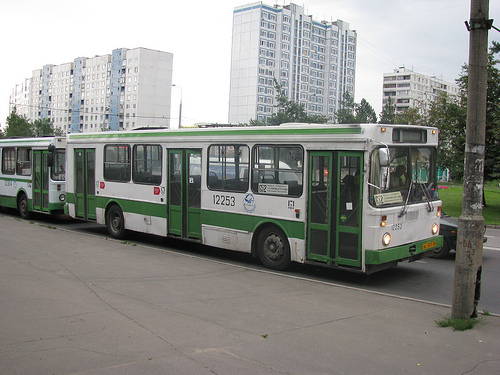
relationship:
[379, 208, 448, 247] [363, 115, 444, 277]
lights on on front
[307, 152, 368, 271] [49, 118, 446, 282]
doors on bus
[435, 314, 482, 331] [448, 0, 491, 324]
grass around pole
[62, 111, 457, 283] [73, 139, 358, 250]
bus has doors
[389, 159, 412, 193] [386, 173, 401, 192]
bus driver on seat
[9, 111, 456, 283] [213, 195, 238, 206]
bus number 12253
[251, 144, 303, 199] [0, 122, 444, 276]
window on bus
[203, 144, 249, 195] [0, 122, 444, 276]
window on bus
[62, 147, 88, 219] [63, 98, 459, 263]
door on a bus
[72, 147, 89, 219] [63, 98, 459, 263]
door on a bus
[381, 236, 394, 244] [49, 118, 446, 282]
headlight on a bus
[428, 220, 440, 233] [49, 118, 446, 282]
headlight on a bus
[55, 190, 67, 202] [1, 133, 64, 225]
headlight on a bus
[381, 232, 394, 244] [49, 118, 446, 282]
headlight on a bus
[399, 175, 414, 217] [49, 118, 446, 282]
windshield wiper on a bus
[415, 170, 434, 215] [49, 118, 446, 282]
windshield wiper on a bus